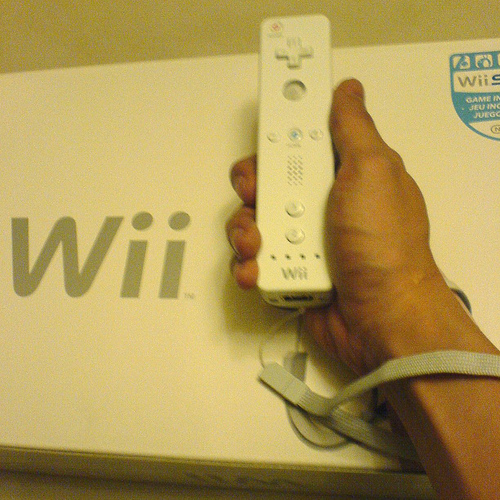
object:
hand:
[227, 78, 499, 499]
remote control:
[253, 14, 335, 307]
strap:
[256, 348, 500, 461]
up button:
[287, 35, 301, 45]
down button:
[288, 57, 300, 67]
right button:
[303, 47, 313, 56]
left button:
[276, 49, 287, 57]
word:
[11, 211, 191, 298]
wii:
[0, 41, 499, 474]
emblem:
[451, 50, 499, 141]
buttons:
[286, 228, 306, 243]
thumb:
[329, 77, 393, 151]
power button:
[268, 21, 281, 33]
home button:
[288, 129, 303, 141]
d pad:
[276, 37, 312, 67]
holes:
[287, 156, 293, 161]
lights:
[269, 254, 277, 261]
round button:
[281, 79, 306, 101]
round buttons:
[267, 130, 280, 143]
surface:
[0, 34, 499, 471]